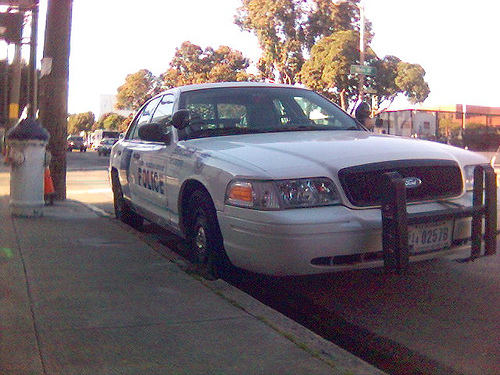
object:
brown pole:
[40, 2, 71, 201]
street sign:
[353, 63, 373, 74]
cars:
[98, 138, 119, 156]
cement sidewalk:
[0, 201, 350, 365]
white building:
[363, 100, 498, 146]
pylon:
[42, 169, 56, 200]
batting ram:
[377, 164, 497, 274]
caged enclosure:
[183, 90, 357, 130]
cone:
[43, 165, 56, 205]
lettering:
[134, 164, 168, 194]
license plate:
[412, 225, 454, 255]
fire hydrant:
[6, 117, 53, 218]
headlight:
[249, 177, 341, 210]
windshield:
[183, 87, 350, 129]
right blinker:
[226, 180, 255, 207]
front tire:
[183, 191, 223, 278]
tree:
[234, 0, 430, 117]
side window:
[143, 94, 174, 143]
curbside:
[113, 217, 171, 263]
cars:
[67, 135, 89, 152]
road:
[75, 153, 105, 193]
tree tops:
[234, 2, 361, 46]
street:
[345, 283, 451, 348]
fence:
[439, 114, 470, 132]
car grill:
[342, 164, 461, 207]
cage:
[333, 157, 463, 209]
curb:
[224, 290, 306, 357]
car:
[109, 81, 492, 279]